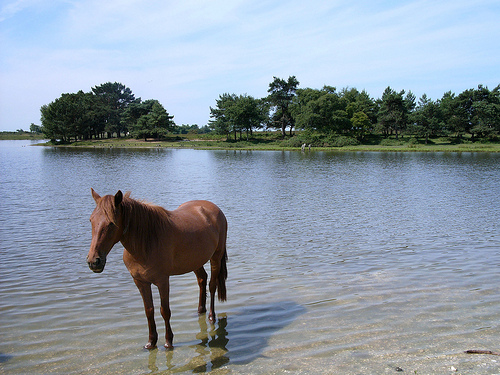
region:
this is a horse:
[79, 176, 239, 355]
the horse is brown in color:
[85, 192, 240, 339]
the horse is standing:
[79, 187, 240, 352]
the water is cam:
[268, 163, 468, 307]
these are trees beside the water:
[58, 92, 497, 137]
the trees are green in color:
[271, 88, 488, 132]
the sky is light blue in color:
[0, 5, 497, 58]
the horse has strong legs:
[134, 283, 179, 334]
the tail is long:
[216, 255, 234, 295]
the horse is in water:
[70, 193, 264, 353]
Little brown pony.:
[82, 186, 229, 348]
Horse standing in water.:
[81, 186, 228, 351]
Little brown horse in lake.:
[82, 189, 227, 353]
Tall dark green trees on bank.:
[204, 91, 273, 142]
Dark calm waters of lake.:
[36, 157, 380, 193]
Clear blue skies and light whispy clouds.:
[111, 9, 463, 54]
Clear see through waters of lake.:
[318, 324, 467, 371]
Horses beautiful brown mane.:
[95, 189, 170, 261]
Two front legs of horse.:
[135, 281, 174, 350]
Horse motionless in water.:
[85, 188, 227, 351]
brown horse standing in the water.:
[35, 65, 410, 355]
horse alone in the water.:
[30, 65, 410, 355]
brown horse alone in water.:
[35, 101, 385, 356]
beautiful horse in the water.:
[35, 85, 400, 356]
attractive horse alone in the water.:
[70, 57, 400, 357]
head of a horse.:
[70, 182, 135, 277]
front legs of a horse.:
[121, 290, 186, 355]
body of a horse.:
[155, 205, 217, 265]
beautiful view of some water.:
[270, 150, 461, 265]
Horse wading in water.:
[85, 185, 231, 349]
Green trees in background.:
[39, 79, 499, 152]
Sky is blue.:
[3, 26, 498, 94]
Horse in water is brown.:
[81, 188, 230, 347]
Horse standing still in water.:
[84, 188, 232, 351]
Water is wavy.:
[279, 186, 495, 322]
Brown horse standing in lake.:
[2, 146, 496, 372]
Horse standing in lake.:
[2, 147, 494, 374]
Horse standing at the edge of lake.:
[4, 146, 499, 373]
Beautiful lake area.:
[0, 75, 497, 371]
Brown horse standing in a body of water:
[84, 183, 237, 353]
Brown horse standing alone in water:
[83, 181, 245, 352]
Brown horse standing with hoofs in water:
[80, 180, 244, 358]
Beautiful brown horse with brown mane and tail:
[82, 180, 257, 353]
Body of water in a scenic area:
[0, 134, 495, 368]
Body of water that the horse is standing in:
[2, 141, 497, 346]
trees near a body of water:
[41, 76, 178, 150]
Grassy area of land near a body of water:
[100, 126, 498, 156]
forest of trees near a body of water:
[212, 72, 497, 142]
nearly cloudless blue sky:
[5, 8, 483, 67]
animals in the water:
[280, 135, 319, 152]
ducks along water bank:
[83, 140, 203, 156]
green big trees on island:
[23, 80, 171, 160]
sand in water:
[310, 297, 498, 373]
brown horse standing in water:
[86, 189, 228, 351]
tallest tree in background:
[256, 74, 298, 136]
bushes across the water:
[281, 131, 357, 146]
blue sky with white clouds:
[0, 1, 497, 132]